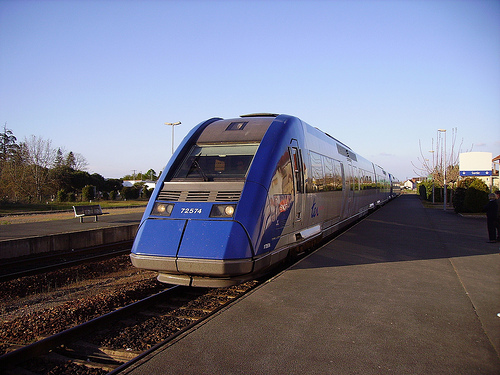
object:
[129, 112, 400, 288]
train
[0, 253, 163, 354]
gravel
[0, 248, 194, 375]
tracks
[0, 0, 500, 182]
sky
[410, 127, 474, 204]
small tree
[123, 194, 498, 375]
pavement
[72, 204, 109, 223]
bench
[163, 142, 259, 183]
windshield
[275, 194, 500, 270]
shadow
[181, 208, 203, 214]
numbers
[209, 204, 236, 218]
left headlight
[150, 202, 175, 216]
right headlight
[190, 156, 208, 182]
windshield wiper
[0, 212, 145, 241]
platform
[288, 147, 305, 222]
door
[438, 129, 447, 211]
light post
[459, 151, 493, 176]
train stop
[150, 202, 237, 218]
two headlights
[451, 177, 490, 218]
hedge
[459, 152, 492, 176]
sign post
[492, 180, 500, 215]
building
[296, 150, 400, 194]
passengers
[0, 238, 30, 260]
concrete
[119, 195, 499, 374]
floor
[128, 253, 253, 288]
edge